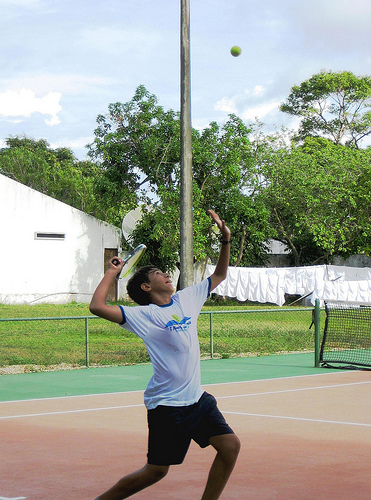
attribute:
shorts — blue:
[133, 391, 232, 465]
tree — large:
[282, 66, 368, 149]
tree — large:
[266, 137, 369, 256]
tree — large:
[87, 83, 177, 192]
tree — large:
[5, 135, 129, 217]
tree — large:
[188, 122, 265, 259]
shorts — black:
[155, 402, 232, 455]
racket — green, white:
[113, 234, 149, 291]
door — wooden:
[100, 244, 120, 303]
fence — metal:
[0, 305, 321, 374]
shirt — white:
[113, 276, 215, 413]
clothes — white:
[202, 265, 368, 310]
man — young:
[88, 211, 238, 498]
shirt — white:
[117, 279, 210, 407]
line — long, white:
[226, 376, 291, 431]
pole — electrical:
[177, 0, 193, 294]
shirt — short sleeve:
[117, 266, 220, 410]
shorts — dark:
[130, 384, 227, 473]